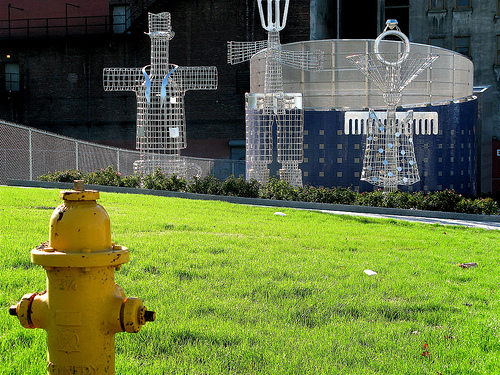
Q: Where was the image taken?
A: It was taken at the park.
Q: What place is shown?
A: It is a park.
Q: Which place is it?
A: It is a park.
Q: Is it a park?
A: Yes, it is a park.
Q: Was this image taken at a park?
A: Yes, it was taken in a park.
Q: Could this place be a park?
A: Yes, it is a park.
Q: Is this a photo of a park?
A: Yes, it is showing a park.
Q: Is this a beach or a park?
A: It is a park.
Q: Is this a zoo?
A: No, it is a park.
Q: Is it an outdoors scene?
A: Yes, it is outdoors.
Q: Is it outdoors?
A: Yes, it is outdoors.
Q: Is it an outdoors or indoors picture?
A: It is outdoors.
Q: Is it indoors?
A: No, it is outdoors.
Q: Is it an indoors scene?
A: No, it is outdoors.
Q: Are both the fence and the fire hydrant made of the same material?
A: Yes, both the fence and the fire hydrant are made of metal.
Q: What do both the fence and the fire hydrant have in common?
A: The material, both the fence and the fire hydrant are metallic.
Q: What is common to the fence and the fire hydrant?
A: The material, both the fence and the fire hydrant are metallic.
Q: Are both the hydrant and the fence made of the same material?
A: Yes, both the hydrant and the fence are made of metal.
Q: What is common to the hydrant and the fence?
A: The material, both the hydrant and the fence are metallic.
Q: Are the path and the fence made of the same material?
A: No, the path is made of concrete and the fence is made of metal.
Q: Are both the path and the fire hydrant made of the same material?
A: No, the path is made of concrete and the fire hydrant is made of metal.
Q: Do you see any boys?
A: No, there are no boys.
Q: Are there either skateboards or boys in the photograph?
A: No, there are no boys or skateboards.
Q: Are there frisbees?
A: No, there are no frisbees.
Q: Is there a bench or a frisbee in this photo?
A: No, there are no frisbees or benches.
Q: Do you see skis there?
A: No, there are no skis.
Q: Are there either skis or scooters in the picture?
A: No, there are no skis or scooters.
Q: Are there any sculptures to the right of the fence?
A: Yes, there is a sculpture to the right of the fence.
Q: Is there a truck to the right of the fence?
A: No, there is a sculpture to the right of the fence.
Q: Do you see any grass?
A: Yes, there is grass.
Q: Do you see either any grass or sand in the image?
A: Yes, there is grass.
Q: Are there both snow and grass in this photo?
A: No, there is grass but no snow.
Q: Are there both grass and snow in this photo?
A: No, there is grass but no snow.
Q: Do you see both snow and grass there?
A: No, there is grass but no snow.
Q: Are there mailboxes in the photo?
A: No, there are no mailboxes.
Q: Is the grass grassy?
A: Yes, the grass is grassy.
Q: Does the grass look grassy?
A: Yes, the grass is grassy.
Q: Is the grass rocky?
A: No, the grass is grassy.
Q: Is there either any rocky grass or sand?
A: No, there is grass but it is grassy.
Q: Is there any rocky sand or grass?
A: No, there is grass but it is grassy.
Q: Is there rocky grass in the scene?
A: No, there is grass but it is grassy.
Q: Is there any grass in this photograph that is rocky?
A: No, there is grass but it is grassy.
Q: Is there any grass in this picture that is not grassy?
A: No, there is grass but it is grassy.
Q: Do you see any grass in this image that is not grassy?
A: No, there is grass but it is grassy.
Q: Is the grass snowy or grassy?
A: The grass is grassy.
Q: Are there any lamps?
A: No, there are no lamps.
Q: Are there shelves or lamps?
A: No, there are no lamps or shelves.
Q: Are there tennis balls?
A: No, there are no tennis balls.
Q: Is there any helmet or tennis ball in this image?
A: No, there are no tennis balls or helmets.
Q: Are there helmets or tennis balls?
A: No, there are no tennis balls or helmets.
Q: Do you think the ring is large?
A: Yes, the ring is large.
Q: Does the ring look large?
A: Yes, the ring is large.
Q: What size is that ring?
A: The ring is large.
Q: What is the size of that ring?
A: The ring is large.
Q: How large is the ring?
A: The ring is large.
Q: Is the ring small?
A: No, the ring is large.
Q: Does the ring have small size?
A: No, the ring is large.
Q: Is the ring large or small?
A: The ring is large.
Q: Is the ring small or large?
A: The ring is large.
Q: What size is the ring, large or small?
A: The ring is large.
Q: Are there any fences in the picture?
A: Yes, there is a fence.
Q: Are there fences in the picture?
A: Yes, there is a fence.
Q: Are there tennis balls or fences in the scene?
A: Yes, there is a fence.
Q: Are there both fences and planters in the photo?
A: No, there is a fence but no planters.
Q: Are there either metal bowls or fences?
A: Yes, there is a metal fence.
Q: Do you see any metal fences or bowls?
A: Yes, there is a metal fence.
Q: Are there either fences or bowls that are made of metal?
A: Yes, the fence is made of metal.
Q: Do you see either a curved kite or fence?
A: Yes, there is a curved fence.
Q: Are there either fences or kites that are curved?
A: Yes, the fence is curved.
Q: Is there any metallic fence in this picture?
A: Yes, there is a metal fence.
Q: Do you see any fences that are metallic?
A: Yes, there is a fence that is metallic.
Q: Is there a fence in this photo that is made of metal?
A: Yes, there is a fence that is made of metal.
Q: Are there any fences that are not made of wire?
A: Yes, there is a fence that is made of metal.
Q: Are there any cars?
A: No, there are no cars.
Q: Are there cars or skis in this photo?
A: No, there are no cars or skis.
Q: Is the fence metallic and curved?
A: Yes, the fence is metallic and curved.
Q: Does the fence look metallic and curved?
A: Yes, the fence is metallic and curved.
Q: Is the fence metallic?
A: Yes, the fence is metallic.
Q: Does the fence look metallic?
A: Yes, the fence is metallic.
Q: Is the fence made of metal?
A: Yes, the fence is made of metal.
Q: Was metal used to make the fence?
A: Yes, the fence is made of metal.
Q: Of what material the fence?
A: The fence is made of metal.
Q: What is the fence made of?
A: The fence is made of metal.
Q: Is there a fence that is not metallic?
A: No, there is a fence but it is metallic.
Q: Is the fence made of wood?
A: No, the fence is made of metal.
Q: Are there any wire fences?
A: No, there is a fence but it is made of metal.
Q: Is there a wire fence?
A: No, there is a fence but it is made of metal.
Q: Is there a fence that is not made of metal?
A: No, there is a fence but it is made of metal.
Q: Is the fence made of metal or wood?
A: The fence is made of metal.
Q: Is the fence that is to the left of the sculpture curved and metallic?
A: Yes, the fence is curved and metallic.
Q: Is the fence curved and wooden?
A: No, the fence is curved but metallic.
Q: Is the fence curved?
A: Yes, the fence is curved.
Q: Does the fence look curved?
A: Yes, the fence is curved.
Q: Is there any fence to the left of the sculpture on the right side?
A: Yes, there is a fence to the left of the sculpture.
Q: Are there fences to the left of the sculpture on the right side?
A: Yes, there is a fence to the left of the sculpture.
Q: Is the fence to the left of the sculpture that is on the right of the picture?
A: Yes, the fence is to the left of the sculpture.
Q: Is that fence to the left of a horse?
A: No, the fence is to the left of the sculpture.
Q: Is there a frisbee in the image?
A: No, there are no frisbees.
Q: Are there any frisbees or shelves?
A: No, there are no frisbees or shelves.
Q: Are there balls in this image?
A: No, there are no balls.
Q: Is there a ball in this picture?
A: No, there are no balls.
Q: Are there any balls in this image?
A: No, there are no balls.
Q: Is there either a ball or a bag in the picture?
A: No, there are no balls or bags.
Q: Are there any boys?
A: No, there are no boys.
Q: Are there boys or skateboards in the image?
A: No, there are no boys or skateboards.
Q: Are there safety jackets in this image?
A: No, there are no safety jackets.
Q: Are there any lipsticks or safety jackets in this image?
A: No, there are no safety jackets or lipsticks.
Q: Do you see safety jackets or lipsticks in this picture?
A: No, there are no safety jackets or lipsticks.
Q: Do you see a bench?
A: No, there are no benches.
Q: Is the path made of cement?
A: Yes, the path is made of cement.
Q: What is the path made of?
A: The path is made of concrete.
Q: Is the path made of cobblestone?
A: No, the path is made of cement.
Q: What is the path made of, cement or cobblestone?
A: The path is made of cement.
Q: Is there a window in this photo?
A: Yes, there are windows.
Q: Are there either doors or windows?
A: Yes, there are windows.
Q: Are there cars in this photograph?
A: No, there are no cars.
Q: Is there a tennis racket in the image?
A: No, there are no rackets.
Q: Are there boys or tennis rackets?
A: No, there are no tennis rackets or boys.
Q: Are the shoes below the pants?
A: Yes, the shoes are below the pants.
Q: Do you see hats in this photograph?
A: Yes, there is a hat.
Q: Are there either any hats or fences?
A: Yes, there is a hat.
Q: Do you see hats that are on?
A: Yes, there is a hat that is on.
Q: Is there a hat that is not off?
A: Yes, there is a hat that is on.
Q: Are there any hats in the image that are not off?
A: Yes, there is a hat that is on.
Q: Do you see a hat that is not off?
A: Yes, there is a hat that is on .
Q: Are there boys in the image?
A: No, there are no boys.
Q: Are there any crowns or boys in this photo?
A: No, there are no boys or crowns.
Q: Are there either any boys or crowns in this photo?
A: No, there are no boys or crowns.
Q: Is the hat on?
A: Yes, the hat is on.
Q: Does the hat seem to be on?
A: Yes, the hat is on.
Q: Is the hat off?
A: No, the hat is on.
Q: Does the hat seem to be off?
A: No, the hat is on.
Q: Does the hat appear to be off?
A: No, the hat is on.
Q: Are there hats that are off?
A: No, there is a hat but it is on.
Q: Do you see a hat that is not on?
A: No, there is a hat but it is on.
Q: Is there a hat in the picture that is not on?
A: No, there is a hat but it is on.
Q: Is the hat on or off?
A: The hat is on.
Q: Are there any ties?
A: Yes, there is a tie.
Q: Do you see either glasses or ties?
A: Yes, there is a tie.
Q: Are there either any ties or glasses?
A: Yes, there is a tie.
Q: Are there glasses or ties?
A: Yes, there is a tie.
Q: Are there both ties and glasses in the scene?
A: No, there is a tie but no glasses.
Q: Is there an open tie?
A: Yes, there is an open tie.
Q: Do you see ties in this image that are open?
A: Yes, there is a tie that is open.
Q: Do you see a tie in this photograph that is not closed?
A: Yes, there is a open tie.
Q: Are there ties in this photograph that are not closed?
A: Yes, there is a open tie.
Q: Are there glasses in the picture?
A: No, there are no glasses.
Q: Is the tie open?
A: Yes, the tie is open.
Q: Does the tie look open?
A: Yes, the tie is open.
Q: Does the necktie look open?
A: Yes, the necktie is open.